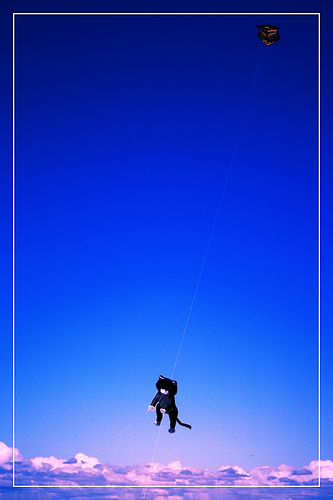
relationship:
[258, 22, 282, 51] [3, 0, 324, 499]
kite in sky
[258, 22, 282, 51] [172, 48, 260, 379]
kite has a string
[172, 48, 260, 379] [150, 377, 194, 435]
string holds cat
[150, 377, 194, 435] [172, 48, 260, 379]
cat held by string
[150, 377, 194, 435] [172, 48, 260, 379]
cat centered in string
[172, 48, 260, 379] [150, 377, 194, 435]
string attached to cat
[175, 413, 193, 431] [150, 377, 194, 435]
tail of cat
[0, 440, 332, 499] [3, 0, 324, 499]
cloud in sky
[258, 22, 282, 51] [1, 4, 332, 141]
parachute at top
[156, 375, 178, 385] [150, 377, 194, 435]
ears of cat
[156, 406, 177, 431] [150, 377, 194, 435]
legs on cat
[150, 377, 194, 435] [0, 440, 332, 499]
cat over cloud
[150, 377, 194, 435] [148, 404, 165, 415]
cat has white paws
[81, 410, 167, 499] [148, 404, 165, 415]
strings on both paws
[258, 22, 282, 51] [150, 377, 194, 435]
kite on cat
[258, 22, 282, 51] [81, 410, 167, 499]
kite has many strings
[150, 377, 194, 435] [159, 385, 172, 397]
cat has white mouth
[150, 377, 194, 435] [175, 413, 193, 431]
cat has tail